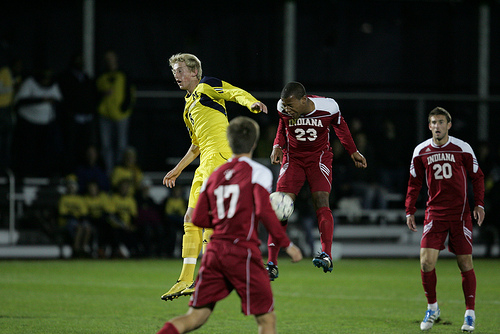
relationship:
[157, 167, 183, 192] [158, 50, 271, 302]
hand of a men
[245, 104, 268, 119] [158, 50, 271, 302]
hand of a men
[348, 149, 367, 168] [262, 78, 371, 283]
hand of a man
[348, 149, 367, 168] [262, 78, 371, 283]
hand of man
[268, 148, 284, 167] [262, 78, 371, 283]
hand of man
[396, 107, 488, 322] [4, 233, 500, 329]
man on field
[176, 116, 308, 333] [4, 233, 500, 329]
man on field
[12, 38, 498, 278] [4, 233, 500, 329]
spectators watching field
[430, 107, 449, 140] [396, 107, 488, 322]
face of man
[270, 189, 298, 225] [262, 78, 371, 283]
soccer ball near man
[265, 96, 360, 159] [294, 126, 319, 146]
shirt with number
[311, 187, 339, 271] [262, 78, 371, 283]
leg of man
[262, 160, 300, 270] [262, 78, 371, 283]
leg of man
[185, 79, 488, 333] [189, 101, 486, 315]
men in uniforms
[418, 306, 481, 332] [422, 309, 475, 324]
shoes have laces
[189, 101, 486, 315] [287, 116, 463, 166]
uniforms say indiana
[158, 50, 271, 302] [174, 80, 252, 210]
men in uniform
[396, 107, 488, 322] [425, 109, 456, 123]
man has hair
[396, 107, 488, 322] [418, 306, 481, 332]
man has shoes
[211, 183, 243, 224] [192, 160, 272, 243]
number on shirt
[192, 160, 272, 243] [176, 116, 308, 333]
shirt of man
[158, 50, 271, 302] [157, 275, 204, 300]
men wearing shoes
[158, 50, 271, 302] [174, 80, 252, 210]
men wearing uniform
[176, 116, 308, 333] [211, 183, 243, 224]
man wearing number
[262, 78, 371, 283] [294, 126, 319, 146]
man wearing number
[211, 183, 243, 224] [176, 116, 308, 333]
number on man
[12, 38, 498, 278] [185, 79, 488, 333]
spectators watching men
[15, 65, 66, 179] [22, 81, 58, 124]
spectator in shirt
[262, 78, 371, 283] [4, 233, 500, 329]
man on field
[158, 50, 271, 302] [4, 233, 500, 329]
men on field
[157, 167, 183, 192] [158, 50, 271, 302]
hand of men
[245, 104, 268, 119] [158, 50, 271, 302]
hand of men